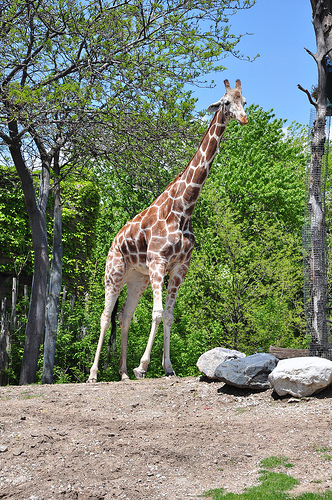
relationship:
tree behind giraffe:
[45, 98, 60, 383] [86, 76, 246, 382]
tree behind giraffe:
[7, 28, 41, 380] [86, 76, 246, 382]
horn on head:
[234, 78, 241, 89] [221, 78, 246, 126]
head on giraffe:
[221, 78, 246, 126] [86, 76, 246, 382]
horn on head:
[222, 78, 231, 91] [221, 78, 246, 126]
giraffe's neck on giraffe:
[171, 109, 225, 226] [86, 76, 246, 382]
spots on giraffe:
[104, 104, 234, 311] [86, 76, 246, 382]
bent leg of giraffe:
[139, 269, 163, 376] [86, 76, 246, 382]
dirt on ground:
[3, 374, 330, 493] [1, 354, 331, 498]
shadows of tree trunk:
[24, 274, 51, 322] [4, 215, 83, 403]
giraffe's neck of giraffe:
[171, 109, 225, 226] [86, 76, 246, 382]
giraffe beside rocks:
[86, 76, 246, 382] [193, 344, 328, 396]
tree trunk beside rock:
[289, 3, 323, 347] [177, 330, 250, 387]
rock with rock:
[268, 353, 329, 398] [212, 355, 277, 388]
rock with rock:
[268, 353, 329, 398] [196, 346, 244, 380]